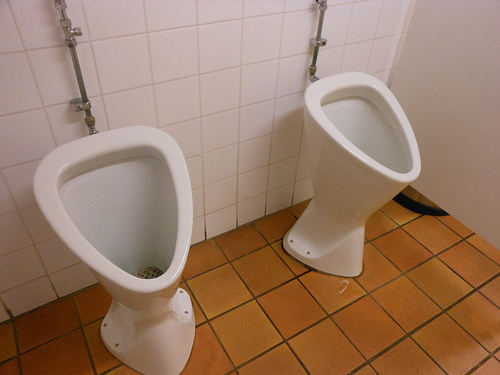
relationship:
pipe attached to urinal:
[54, 1, 96, 135] [32, 124, 195, 374]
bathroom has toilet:
[3, 63, 474, 353] [281, 68, 423, 279]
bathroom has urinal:
[3, 63, 474, 353] [32, 124, 195, 374]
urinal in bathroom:
[30, 123, 210, 373] [1, 3, 496, 374]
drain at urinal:
[137, 266, 166, 282] [30, 22, 227, 364]